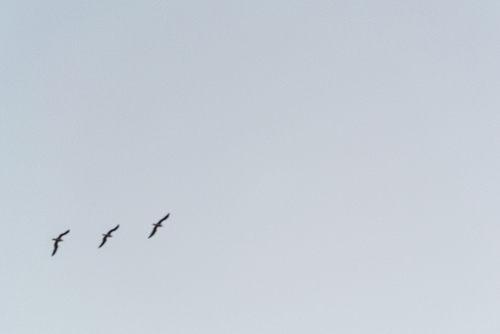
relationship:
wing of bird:
[158, 212, 170, 222] [148, 212, 171, 237]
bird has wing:
[148, 212, 171, 237] [158, 212, 170, 222]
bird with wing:
[148, 212, 171, 237] [158, 212, 170, 222]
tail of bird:
[151, 221, 157, 228] [148, 212, 171, 237]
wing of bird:
[109, 224, 119, 234] [97, 222, 120, 247]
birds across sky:
[48, 210, 172, 255] [1, 1, 499, 333]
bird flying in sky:
[148, 212, 171, 237] [136, 112, 346, 219]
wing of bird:
[158, 212, 170, 222] [148, 212, 170, 238]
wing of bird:
[158, 212, 170, 222] [78, 214, 139, 247]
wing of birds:
[158, 212, 170, 222] [50, 228, 72, 256]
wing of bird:
[158, 212, 170, 222] [144, 211, 205, 271]